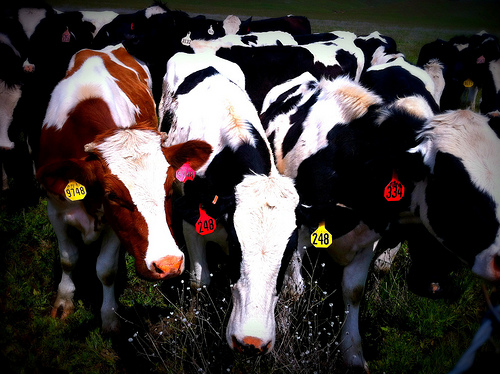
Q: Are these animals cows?
A: Yes, all the animals are cows.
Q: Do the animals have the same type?
A: Yes, all the animals are cows.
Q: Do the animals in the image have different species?
A: No, all the animals are cows.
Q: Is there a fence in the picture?
A: No, there are no fences.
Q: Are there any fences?
A: No, there are no fences.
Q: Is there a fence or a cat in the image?
A: No, there are no fences or cats.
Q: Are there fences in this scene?
A: No, there are no fences.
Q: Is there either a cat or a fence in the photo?
A: No, there are no fences or cats.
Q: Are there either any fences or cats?
A: No, there are no fences or cats.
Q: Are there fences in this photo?
A: No, there are no fences.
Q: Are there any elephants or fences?
A: No, there are no fences or elephants.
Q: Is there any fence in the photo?
A: No, there are no fences.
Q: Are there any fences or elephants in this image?
A: No, there are no fences or elephants.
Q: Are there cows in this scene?
A: Yes, there are cows.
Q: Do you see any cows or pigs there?
A: Yes, there are cows.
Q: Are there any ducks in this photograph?
A: No, there are no ducks.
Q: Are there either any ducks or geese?
A: No, there are no ducks or geese.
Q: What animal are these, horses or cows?
A: These are cows.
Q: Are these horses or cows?
A: These are cows.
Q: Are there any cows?
A: Yes, there is a cow.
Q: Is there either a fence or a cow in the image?
A: Yes, there is a cow.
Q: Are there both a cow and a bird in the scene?
A: No, there is a cow but no birds.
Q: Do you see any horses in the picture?
A: No, there are no horses.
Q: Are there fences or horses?
A: No, there are no horses or fences.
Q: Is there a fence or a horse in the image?
A: No, there are no horses or fences.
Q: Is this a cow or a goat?
A: This is a cow.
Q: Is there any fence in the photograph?
A: No, there are no fences.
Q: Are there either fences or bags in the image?
A: No, there are no fences or bags.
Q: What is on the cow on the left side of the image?
A: The tag is on the cow.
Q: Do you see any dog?
A: No, there are no dogs.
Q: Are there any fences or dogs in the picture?
A: No, there are no dogs or fences.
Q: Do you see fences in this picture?
A: No, there are no fences.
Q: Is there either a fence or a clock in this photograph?
A: No, there are no fences or clocks.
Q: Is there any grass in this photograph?
A: Yes, there is grass.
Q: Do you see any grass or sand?
A: Yes, there is grass.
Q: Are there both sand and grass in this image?
A: No, there is grass but no sand.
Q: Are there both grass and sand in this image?
A: No, there is grass but no sand.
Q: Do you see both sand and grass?
A: No, there is grass but no sand.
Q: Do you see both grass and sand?
A: No, there is grass but no sand.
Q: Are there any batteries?
A: No, there are no batteries.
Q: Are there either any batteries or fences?
A: No, there are no batteries or fences.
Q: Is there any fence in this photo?
A: No, there are no fences.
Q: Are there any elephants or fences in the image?
A: No, there are no fences or elephants.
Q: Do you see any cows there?
A: Yes, there is a cow.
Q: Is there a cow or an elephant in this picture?
A: Yes, there is a cow.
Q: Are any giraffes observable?
A: No, there are no giraffes.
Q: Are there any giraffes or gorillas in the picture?
A: No, there are no giraffes or gorillas.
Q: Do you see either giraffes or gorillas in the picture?
A: No, there are no giraffes or gorillas.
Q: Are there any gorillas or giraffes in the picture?
A: No, there are no giraffes or gorillas.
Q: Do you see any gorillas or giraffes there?
A: No, there are no giraffes or gorillas.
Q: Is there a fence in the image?
A: No, there are no fences.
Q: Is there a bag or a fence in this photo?
A: No, there are no fences or bags.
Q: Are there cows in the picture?
A: Yes, there is a cow.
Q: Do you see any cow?
A: Yes, there is a cow.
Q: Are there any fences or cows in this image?
A: Yes, there is a cow.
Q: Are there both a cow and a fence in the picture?
A: No, there is a cow but no fences.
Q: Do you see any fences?
A: No, there are no fences.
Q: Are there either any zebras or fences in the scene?
A: No, there are no fences or zebras.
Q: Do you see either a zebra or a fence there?
A: No, there are no fences or zebras.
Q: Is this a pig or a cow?
A: This is a cow.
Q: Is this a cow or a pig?
A: This is a cow.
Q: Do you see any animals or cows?
A: Yes, there is a cow.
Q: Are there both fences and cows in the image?
A: No, there is a cow but no fences.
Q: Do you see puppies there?
A: No, there are no puppies.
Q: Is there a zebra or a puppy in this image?
A: No, there are no puppies or zebras.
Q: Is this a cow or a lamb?
A: This is a cow.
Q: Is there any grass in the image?
A: Yes, there is grass.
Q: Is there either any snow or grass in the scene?
A: Yes, there is grass.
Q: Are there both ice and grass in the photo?
A: No, there is grass but no ice.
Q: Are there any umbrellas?
A: No, there are no umbrellas.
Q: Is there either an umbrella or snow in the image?
A: No, there are no umbrellas or snow.